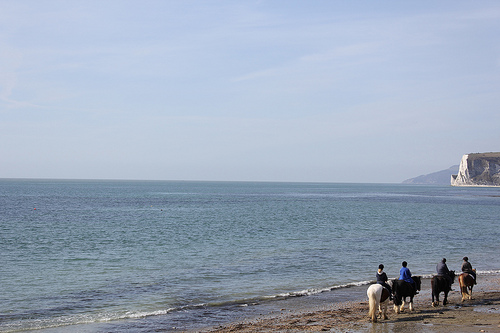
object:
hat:
[378, 263, 386, 271]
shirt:
[397, 267, 415, 282]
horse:
[364, 277, 402, 324]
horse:
[386, 275, 423, 314]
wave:
[0, 271, 366, 329]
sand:
[133, 271, 500, 332]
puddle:
[471, 302, 500, 315]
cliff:
[448, 172, 458, 185]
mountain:
[450, 150, 500, 187]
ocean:
[0, 177, 500, 333]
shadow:
[379, 313, 440, 324]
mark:
[419, 317, 435, 325]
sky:
[2, 2, 498, 153]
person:
[374, 260, 394, 302]